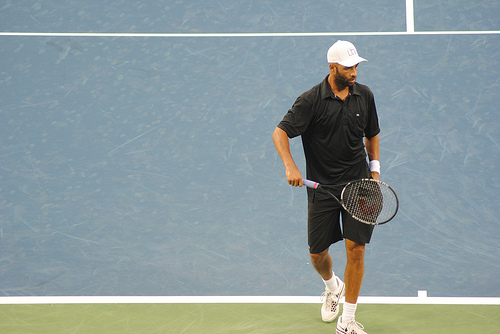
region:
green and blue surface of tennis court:
[0, 1, 498, 332]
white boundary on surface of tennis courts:
[1, 0, 498, 305]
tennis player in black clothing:
[275, 39, 398, 332]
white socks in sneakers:
[320, 272, 361, 332]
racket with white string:
[300, 177, 400, 225]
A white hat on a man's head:
[325, 35, 367, 66]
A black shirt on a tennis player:
[277, 70, 378, 177]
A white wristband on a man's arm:
[367, 154, 383, 176]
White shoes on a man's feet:
[317, 277, 369, 331]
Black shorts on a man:
[302, 180, 374, 245]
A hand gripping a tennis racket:
[287, 167, 300, 187]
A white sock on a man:
[340, 296, 357, 317]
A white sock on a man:
[320, 272, 336, 285]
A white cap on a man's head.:
[325, 39, 366, 66]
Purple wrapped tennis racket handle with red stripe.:
[298, 176, 320, 190]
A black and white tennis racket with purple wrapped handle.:
[298, 177, 399, 225]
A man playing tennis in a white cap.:
[270, 40, 382, 332]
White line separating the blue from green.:
[0, 296, 498, 304]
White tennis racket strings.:
[344, 182, 395, 223]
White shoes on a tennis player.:
[320, 277, 367, 332]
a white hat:
[330, 42, 368, 72]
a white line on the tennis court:
[150, 294, 193, 304]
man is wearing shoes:
[320, 288, 342, 321]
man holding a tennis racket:
[288, 163, 313, 192]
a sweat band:
[370, 160, 380, 170]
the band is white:
[368, 156, 378, 174]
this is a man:
[256, 17, 416, 326]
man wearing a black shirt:
[268, 63, 395, 201]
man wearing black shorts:
[285, 149, 390, 251]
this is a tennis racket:
[280, 146, 409, 233]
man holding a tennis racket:
[265, 33, 399, 330]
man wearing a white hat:
[323, 20, 368, 91]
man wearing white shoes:
[308, 268, 375, 332]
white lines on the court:
[16, 268, 486, 328]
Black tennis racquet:
[297, 173, 400, 228]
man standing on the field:
[317, 43, 373, 330]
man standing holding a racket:
[269, 37, 386, 325]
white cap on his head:
[325, 40, 373, 88]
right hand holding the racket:
[274, 123, 390, 225]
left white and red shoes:
[316, 283, 336, 321]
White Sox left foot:
[322, 275, 337, 290]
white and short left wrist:
[368, 155, 385, 170]